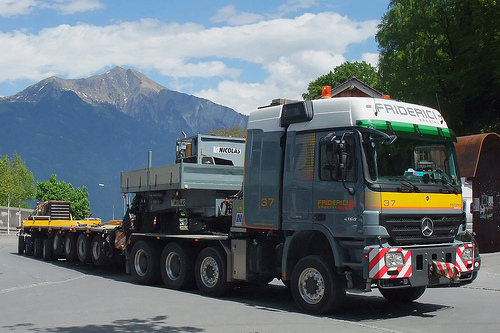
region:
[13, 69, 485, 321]
A truck in the foreground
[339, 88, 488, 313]
A front view of a truck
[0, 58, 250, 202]
A mountain in the background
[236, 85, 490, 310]
The truck is gray in color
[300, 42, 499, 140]
A tree in the background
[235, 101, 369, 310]
A side angle of a truck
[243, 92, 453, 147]
Top of the truck is white and green in color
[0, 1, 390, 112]
Sky in the background is cloudy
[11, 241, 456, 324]
Truck is casting a shadow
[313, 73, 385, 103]
The top of a building in the background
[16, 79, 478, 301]
this is a truck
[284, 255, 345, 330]
a wheel on a truck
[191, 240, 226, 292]
a wheel on a truck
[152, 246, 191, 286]
a wheel on a truck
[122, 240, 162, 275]
a wheel on a truck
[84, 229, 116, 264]
a wheel on a truck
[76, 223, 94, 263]
a wheel on a truck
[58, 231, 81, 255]
a wheel on a truck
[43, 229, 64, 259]
a wheel on a truck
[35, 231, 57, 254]
a wheel on a truck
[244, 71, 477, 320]
green truck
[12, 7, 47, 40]
white clouds in blue sky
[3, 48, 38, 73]
white clouds in blue sky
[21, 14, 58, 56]
white clouds in blue sky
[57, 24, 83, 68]
white clouds in blue sky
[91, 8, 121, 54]
white clouds in blue sky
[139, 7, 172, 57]
white clouds in blue sky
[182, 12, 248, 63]
white clouds in blue sky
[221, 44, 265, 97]
white clouds in blue sky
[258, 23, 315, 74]
white clouds in blue sky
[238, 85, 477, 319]
white and gray track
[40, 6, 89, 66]
white clouds in blue sky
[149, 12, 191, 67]
white clouds in blue sky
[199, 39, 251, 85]
white clouds in blue sky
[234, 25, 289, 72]
white clouds in blue sky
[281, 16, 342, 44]
white clouds in blue sky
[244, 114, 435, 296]
the truck is gray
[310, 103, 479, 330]
the truck is gray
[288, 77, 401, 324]
the truck is gray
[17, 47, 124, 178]
a mountain in the distance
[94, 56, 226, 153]
a mountain in the distance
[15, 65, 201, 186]
a mountain in the distance